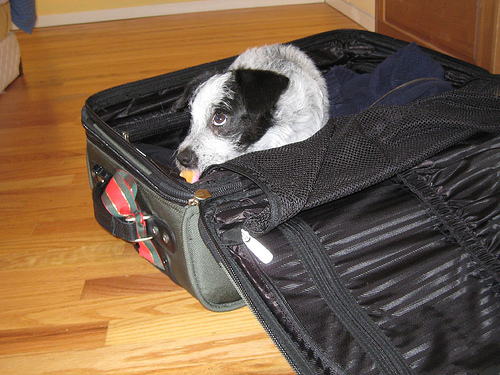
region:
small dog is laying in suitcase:
[38, 35, 465, 273]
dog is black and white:
[157, 40, 334, 179]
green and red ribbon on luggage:
[87, 159, 173, 284]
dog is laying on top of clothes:
[175, 37, 468, 142]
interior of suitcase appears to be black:
[293, 130, 464, 354]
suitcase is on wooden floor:
[18, 77, 98, 338]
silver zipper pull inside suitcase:
[215, 205, 290, 281]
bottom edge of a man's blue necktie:
[8, 0, 58, 52]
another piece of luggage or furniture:
[1, 16, 32, 86]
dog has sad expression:
[144, 66, 282, 165]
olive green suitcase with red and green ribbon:
[68, 30, 489, 347]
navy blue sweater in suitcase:
[278, 26, 465, 144]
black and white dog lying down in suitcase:
[173, 34, 340, 189]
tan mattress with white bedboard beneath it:
[0, 0, 40, 92]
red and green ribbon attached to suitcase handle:
[77, 156, 176, 285]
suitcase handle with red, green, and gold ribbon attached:
[79, 157, 182, 290]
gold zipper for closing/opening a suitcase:
[167, 184, 222, 217]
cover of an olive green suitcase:
[197, 122, 494, 369]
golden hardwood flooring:
[12, 230, 232, 374]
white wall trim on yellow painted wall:
[32, 0, 270, 52]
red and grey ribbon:
[90, 167, 150, 266]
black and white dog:
[168, 41, 337, 186]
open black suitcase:
[82, 17, 483, 373]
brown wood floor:
[0, 5, 325, 362]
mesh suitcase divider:
[243, 73, 491, 223]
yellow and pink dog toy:
[177, 163, 204, 190]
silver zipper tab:
[240, 227, 276, 271]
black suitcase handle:
[89, 177, 144, 245]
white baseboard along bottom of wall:
[17, 0, 350, 25]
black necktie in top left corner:
[8, 2, 43, 37]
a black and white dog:
[130, 36, 386, 177]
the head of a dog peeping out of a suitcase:
[157, 36, 307, 194]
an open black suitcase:
[77, 38, 499, 330]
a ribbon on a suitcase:
[95, 164, 189, 268]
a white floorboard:
[37, 1, 307, 11]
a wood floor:
[0, 1, 325, 362]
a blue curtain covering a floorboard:
[6, 5, 53, 41]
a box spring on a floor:
[0, 19, 52, 101]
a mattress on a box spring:
[4, 0, 21, 43]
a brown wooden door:
[369, 0, 495, 68]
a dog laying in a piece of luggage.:
[154, 34, 345, 226]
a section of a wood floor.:
[0, 302, 127, 362]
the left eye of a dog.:
[203, 101, 243, 136]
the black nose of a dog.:
[171, 147, 206, 174]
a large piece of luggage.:
[81, 26, 498, 373]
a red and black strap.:
[92, 167, 161, 271]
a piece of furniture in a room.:
[4, 0, 64, 114]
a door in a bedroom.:
[373, 5, 498, 95]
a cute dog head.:
[175, 74, 295, 213]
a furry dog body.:
[224, 54, 338, 154]